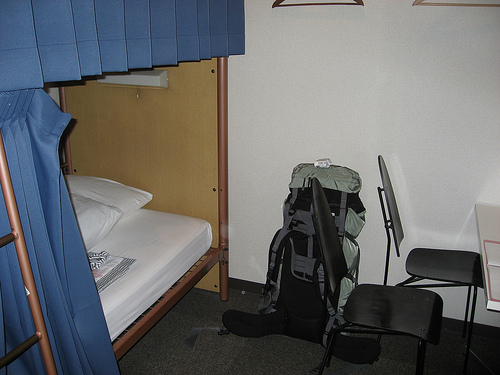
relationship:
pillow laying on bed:
[63, 173, 153, 219] [87, 207, 214, 343]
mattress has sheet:
[86, 208, 214, 342] [86, 208, 213, 343]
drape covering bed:
[1, 88, 122, 374] [87, 207, 214, 343]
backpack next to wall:
[218, 158, 382, 365] [229, 0, 499, 329]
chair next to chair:
[376, 154, 485, 366] [309, 177, 444, 375]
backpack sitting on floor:
[218, 158, 382, 365] [118, 286, 500, 375]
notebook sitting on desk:
[482, 238, 500, 302] [475, 202, 500, 312]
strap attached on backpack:
[259, 226, 294, 314] [218, 158, 382, 365]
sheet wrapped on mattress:
[86, 208, 213, 343] [86, 208, 214, 342]